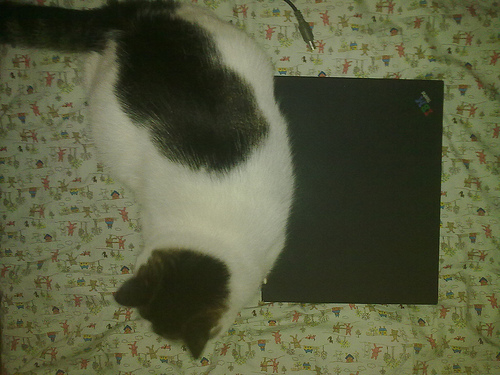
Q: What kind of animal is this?
A: Cat.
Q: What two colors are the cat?
A: Black and white.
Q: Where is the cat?
A: On top of sheet.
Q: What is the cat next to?
A: Black laptop.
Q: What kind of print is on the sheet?
A: Floral.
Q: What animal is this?
A: A cat.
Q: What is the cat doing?
A: Lying down.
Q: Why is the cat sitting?
A: To rest.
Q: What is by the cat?
A: A laptop.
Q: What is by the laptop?
A: A cord.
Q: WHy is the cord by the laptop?
A: To charge it.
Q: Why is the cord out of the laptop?
A: It fell out.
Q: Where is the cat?
A: On a bed.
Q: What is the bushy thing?
A: A tail.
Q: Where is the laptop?
A: On a bed.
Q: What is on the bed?
A: The cat.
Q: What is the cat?
A: Black and white.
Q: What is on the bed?
A: The laptop.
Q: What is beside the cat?
A: The laptop.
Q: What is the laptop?
A: Black.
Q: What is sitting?
A: The cat.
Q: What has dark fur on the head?
A: The cat.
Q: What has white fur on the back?
A: The cat.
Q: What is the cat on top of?
A: A laptop.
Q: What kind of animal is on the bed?
A: Cat.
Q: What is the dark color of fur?
A: Gray.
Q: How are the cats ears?
A: Furry.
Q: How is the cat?
A: Laying.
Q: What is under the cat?
A: Laptop.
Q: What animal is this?
A: Cat.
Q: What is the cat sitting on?
A: Blanket.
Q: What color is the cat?
A: Black and white.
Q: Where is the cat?
A: Near a computer.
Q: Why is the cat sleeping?
A: He is tired.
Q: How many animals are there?
A: One.